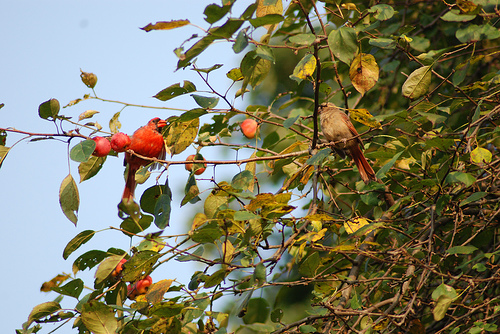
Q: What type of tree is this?
A: Apple.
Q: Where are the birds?
A: On the branch.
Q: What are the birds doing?
A: Sitting down.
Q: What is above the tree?
A: The sky.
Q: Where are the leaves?
A: On the branches.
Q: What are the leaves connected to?
A: The branches.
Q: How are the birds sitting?
A: Their feet are on the branches.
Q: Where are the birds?
A: On the same branch.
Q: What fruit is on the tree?
A: Apples.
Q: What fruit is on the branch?
A: Apples.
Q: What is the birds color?
A: Red.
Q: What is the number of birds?
A: Two.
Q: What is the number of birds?
A: Two.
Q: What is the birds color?
A: Red.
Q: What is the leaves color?
A: Green.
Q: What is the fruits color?
A: Red.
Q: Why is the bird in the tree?
A: It's looking for food.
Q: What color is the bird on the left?
A: Red.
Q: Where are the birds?
A: In a tree.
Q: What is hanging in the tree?
A: Fruit.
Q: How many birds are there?
A: Two.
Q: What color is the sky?
A: Blue.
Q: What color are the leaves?
A: Green.